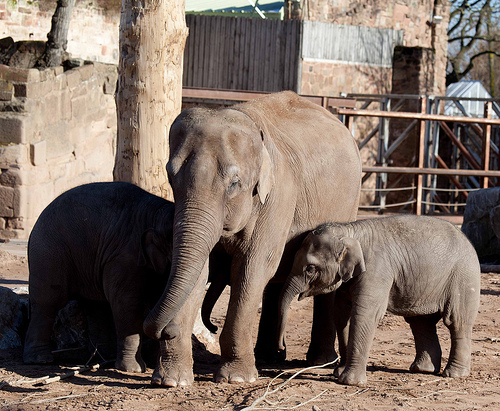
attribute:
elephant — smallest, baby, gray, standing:
[273, 213, 479, 390]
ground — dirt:
[0, 243, 499, 410]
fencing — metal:
[335, 93, 500, 219]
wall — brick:
[296, 1, 451, 207]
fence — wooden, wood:
[180, 13, 301, 105]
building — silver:
[440, 81, 499, 214]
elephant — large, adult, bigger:
[143, 88, 364, 388]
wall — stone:
[0, 1, 123, 66]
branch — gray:
[41, 358, 116, 386]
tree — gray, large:
[112, 0, 189, 206]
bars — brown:
[179, 86, 356, 109]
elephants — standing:
[21, 88, 484, 392]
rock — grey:
[458, 185, 499, 272]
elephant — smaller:
[18, 180, 231, 375]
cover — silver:
[301, 18, 402, 70]